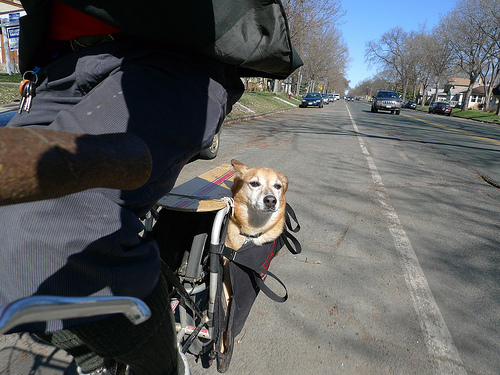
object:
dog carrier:
[215, 199, 304, 337]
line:
[338, 101, 472, 375]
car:
[371, 90, 401, 115]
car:
[298, 91, 323, 108]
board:
[161, 156, 255, 215]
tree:
[360, 1, 498, 104]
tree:
[247, 11, 352, 101]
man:
[0, 0, 307, 375]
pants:
[0, 66, 229, 367]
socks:
[54, 328, 110, 374]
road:
[0, 118, 500, 375]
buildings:
[415, 75, 500, 117]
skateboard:
[153, 163, 257, 214]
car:
[429, 102, 452, 117]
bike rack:
[0, 157, 303, 375]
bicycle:
[1, 161, 288, 371]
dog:
[220, 157, 290, 266]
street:
[0, 119, 500, 375]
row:
[413, 77, 500, 117]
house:
[418, 78, 500, 109]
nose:
[263, 193, 276, 206]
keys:
[18, 65, 40, 114]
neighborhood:
[1, 0, 500, 299]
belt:
[14, 31, 224, 58]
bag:
[206, 200, 302, 343]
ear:
[230, 158, 248, 176]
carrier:
[150, 184, 300, 375]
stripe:
[157, 163, 244, 213]